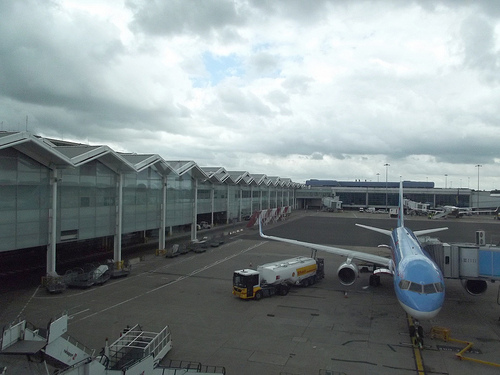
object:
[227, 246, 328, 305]
fuel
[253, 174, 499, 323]
airplane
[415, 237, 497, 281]
passenger tunnel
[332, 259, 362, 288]
turbine engines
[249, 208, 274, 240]
tip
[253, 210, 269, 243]
upwards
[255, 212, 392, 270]
wing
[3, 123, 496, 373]
airport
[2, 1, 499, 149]
sky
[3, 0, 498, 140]
overcast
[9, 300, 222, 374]
staircase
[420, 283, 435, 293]
front windows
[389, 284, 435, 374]
line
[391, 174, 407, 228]
tail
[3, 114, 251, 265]
left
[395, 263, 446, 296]
cockpit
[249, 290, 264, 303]
wheels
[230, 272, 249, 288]
windshields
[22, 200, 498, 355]
tarmac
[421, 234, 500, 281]
ramp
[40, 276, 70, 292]
equiptment